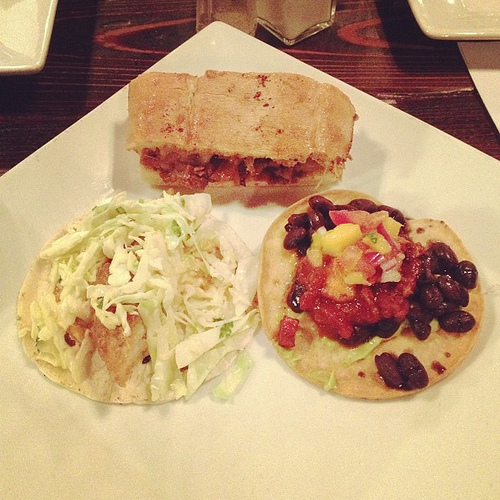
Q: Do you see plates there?
A: Yes, there is a plate.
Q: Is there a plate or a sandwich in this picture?
A: Yes, there is a plate.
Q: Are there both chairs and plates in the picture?
A: No, there is a plate but no chairs.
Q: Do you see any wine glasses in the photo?
A: No, there are no wine glasses.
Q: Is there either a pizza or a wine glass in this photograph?
A: No, there are no wine glasses or pizzas.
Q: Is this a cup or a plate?
A: This is a plate.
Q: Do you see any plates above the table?
A: Yes, there is a plate above the table.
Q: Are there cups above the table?
A: No, there is a plate above the table.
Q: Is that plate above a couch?
A: No, the plate is above the table.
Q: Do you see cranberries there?
A: No, there are no cranberries.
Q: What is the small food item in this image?
A: The food item is a tortilla.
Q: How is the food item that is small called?
A: The food item is a tortilla.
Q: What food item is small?
A: The food item is a tortilla.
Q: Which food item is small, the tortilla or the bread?
A: The tortilla is small.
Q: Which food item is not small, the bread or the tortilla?
A: The bread is not small.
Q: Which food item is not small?
A: The food item is a bread.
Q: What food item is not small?
A: The food item is a bread.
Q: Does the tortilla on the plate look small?
A: Yes, the tortilla is small.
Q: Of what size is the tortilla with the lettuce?
A: The tortilla is small.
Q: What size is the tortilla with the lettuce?
A: The tortilla is small.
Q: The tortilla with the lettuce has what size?
A: The tortilla is small.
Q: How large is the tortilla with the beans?
A: The tortilla is small.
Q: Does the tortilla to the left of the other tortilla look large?
A: No, the tortilla is small.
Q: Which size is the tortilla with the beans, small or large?
A: The tortilla is small.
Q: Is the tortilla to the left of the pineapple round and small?
A: Yes, the tortilla is round and small.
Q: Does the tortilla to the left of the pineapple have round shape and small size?
A: Yes, the tortilla is round and small.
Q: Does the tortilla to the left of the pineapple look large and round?
A: No, the tortilla is round but small.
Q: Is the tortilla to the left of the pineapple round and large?
A: No, the tortilla is round but small.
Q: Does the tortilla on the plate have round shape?
A: Yes, the tortilla is round.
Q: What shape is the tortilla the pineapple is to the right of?
A: The tortilla is round.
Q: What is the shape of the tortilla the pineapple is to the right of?
A: The tortilla is round.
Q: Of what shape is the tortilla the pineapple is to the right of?
A: The tortilla is round.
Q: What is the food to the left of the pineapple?
A: The food is a tortilla.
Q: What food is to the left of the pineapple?
A: The food is a tortilla.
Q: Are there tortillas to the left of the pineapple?
A: Yes, there is a tortilla to the left of the pineapple.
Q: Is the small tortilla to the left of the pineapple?
A: Yes, the tortilla is to the left of the pineapple.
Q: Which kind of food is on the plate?
A: The food is a tortilla.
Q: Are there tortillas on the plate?
A: Yes, there is a tortilla on the plate.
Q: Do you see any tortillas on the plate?
A: Yes, there is a tortilla on the plate.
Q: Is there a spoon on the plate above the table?
A: No, there is a tortilla on the plate.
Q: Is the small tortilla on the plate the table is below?
A: Yes, the tortilla is on the plate.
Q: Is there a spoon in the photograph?
A: No, there are no spoons.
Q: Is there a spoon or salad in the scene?
A: No, there are no spoons or salad.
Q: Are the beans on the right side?
A: Yes, the beans are on the right of the image.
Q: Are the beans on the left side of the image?
A: No, the beans are on the right of the image.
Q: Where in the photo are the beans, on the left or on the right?
A: The beans are on the right of the image.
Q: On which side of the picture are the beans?
A: The beans are on the right of the image.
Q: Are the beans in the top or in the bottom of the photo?
A: The beans are in the bottom of the image.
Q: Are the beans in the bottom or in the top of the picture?
A: The beans are in the bottom of the image.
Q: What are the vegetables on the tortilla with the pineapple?
A: The vegetables are beans.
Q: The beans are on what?
A: The beans are on the tortilla.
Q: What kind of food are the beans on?
A: The beans are on the tortilla.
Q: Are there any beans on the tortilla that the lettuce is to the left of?
A: Yes, there are beans on the tortilla.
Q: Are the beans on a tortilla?
A: Yes, the beans are on a tortilla.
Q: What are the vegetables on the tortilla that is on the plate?
A: The vegetables are beans.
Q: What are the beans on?
A: The beans are on the tortilla.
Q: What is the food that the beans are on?
A: The food is a tortilla.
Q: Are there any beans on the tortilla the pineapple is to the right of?
A: Yes, there are beans on the tortilla.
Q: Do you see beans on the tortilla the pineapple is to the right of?
A: Yes, there are beans on the tortilla.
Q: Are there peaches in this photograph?
A: No, there are no peaches.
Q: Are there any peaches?
A: No, there are no peaches.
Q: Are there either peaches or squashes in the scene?
A: No, there are no peaches or squashes.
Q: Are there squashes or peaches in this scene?
A: No, there are no peaches or squashes.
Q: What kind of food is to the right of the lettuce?
A: The food is a tortilla.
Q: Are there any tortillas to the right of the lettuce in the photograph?
A: Yes, there is a tortilla to the right of the lettuce.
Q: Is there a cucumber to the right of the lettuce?
A: No, there is a tortilla to the right of the lettuce.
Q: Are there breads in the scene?
A: Yes, there is a bread.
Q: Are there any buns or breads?
A: Yes, there is a bread.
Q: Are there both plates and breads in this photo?
A: Yes, there are both a bread and a plate.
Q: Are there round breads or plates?
A: Yes, there is a round bread.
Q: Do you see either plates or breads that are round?
A: Yes, the bread is round.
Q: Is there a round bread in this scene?
A: Yes, there is a round bread.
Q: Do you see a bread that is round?
A: Yes, there is a bread that is round.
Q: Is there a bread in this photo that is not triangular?
A: Yes, there is a round bread.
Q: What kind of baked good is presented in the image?
A: The baked good is a bread.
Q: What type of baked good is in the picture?
A: The baked good is a bread.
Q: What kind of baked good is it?
A: The food is a bread.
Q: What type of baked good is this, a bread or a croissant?
A: That is a bread.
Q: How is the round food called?
A: The food is a bread.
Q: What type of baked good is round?
A: The baked good is a bread.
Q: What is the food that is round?
A: The food is a bread.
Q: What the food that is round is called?
A: The food is a bread.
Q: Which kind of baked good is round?
A: The baked good is a bread.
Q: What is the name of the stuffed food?
A: The food is a bread.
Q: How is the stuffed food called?
A: The food is a bread.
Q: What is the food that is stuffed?
A: The food is a bread.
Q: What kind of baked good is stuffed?
A: The baked good is a bread.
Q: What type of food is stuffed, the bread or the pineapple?
A: The bread is stuffed.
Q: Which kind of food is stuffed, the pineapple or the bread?
A: The bread is stuffed.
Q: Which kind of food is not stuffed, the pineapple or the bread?
A: The pineapple is not stuffed.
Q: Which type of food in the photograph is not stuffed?
A: The food is a pineapple.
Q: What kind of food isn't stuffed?
A: The food is a pineapple.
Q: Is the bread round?
A: Yes, the bread is round.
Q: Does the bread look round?
A: Yes, the bread is round.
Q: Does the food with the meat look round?
A: Yes, the bread is round.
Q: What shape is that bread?
A: The bread is round.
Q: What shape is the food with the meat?
A: The bread is round.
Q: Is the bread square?
A: No, the bread is round.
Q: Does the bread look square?
A: No, the bread is round.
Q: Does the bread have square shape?
A: No, the bread is round.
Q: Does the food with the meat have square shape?
A: No, the bread is round.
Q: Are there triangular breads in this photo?
A: No, there is a bread but it is round.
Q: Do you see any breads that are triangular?
A: No, there is a bread but it is round.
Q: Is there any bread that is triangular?
A: No, there is a bread but it is round.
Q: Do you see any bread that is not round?
A: No, there is a bread but it is round.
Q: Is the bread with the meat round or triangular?
A: The bread is round.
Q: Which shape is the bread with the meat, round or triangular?
A: The bread is round.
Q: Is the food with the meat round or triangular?
A: The bread is round.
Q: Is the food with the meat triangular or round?
A: The bread is round.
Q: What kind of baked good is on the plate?
A: The food is a bread.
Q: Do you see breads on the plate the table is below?
A: Yes, there is a bread on the plate.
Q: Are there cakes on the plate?
A: No, there is a bread on the plate.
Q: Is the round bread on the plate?
A: Yes, the bread is on the plate.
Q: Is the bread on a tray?
A: No, the bread is on the plate.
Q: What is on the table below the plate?
A: The bread is on the table.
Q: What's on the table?
A: The bread is on the table.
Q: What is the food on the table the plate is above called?
A: The food is a bread.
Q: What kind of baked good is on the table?
A: The food is a bread.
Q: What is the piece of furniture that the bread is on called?
A: The piece of furniture is a table.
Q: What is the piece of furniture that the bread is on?
A: The piece of furniture is a table.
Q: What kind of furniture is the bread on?
A: The bread is on the table.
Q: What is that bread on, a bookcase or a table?
A: The bread is on a table.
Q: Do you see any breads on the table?
A: Yes, there is a bread on the table.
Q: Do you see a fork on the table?
A: No, there is a bread on the table.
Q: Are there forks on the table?
A: No, there is a bread on the table.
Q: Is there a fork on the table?
A: No, there is a bread on the table.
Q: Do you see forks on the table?
A: No, there is a bread on the table.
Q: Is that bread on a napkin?
A: No, the bread is on the table.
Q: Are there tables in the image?
A: Yes, there is a table.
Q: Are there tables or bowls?
A: Yes, there is a table.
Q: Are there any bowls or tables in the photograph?
A: Yes, there is a table.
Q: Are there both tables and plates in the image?
A: Yes, there are both a table and a plate.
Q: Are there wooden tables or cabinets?
A: Yes, there is a wood table.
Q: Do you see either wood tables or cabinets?
A: Yes, there is a wood table.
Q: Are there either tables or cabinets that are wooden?
A: Yes, the table is wooden.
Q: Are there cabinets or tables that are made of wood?
A: Yes, the table is made of wood.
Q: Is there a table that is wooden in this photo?
A: Yes, there is a wood table.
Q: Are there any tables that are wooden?
A: Yes, there is a table that is wooden.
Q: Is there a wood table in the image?
A: Yes, there is a table that is made of wood.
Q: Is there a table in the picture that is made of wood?
A: Yes, there is a table that is made of wood.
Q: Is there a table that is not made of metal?
A: Yes, there is a table that is made of wood.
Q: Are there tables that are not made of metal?
A: Yes, there is a table that is made of wood.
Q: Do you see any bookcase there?
A: No, there are no bookcases.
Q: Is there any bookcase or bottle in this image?
A: No, there are no bookcases or bottles.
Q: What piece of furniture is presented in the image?
A: The piece of furniture is a table.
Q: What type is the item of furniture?
A: The piece of furniture is a table.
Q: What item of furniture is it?
A: The piece of furniture is a table.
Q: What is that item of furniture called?
A: This is a table.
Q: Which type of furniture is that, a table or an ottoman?
A: This is a table.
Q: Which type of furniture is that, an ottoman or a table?
A: This is a table.